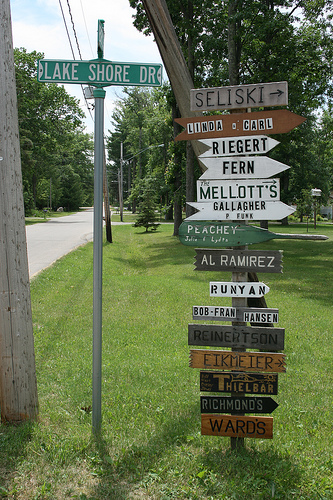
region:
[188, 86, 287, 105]
Sign for the Seliski family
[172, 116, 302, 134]
Sign for Linda and Carl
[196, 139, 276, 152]
Sign for the Riegert Family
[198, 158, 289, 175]
Sign for the Fern family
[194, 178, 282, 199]
Sign for the Mellott famliy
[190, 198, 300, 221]
Sign for the Gallagher family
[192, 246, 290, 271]
Sign for Al Ramirez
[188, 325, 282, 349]
Sign for the Reinertson family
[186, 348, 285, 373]
Sign for the Eikmeier family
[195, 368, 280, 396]
Sign for the Thielbar family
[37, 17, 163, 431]
Green street sign with white lettering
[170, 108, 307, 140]
Brown arrow sign with white and black name letters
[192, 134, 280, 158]
White arrow sign with black letters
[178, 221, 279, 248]
Green arrow sign with white letters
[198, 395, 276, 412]
Black arrow sign with white letters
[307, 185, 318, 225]
White bird house on a pole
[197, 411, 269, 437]
Wood sign with black letters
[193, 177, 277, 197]
White rectangle sign with black letters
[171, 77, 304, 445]
Fifteen signs on a pole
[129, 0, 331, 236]
Several tall green trees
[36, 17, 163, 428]
street signs on a pole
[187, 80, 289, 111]
rectangular wooden sign at the top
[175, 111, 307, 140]
brown arrow-shaped sign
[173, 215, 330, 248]
green wooden paddle sign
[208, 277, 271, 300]
small white arrow-shaped sign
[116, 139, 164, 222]
streetlight beside the road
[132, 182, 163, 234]
small pine tree near the road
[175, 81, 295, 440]
stack of signs with the residents' names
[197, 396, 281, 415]
black arrow-shaped sign towards the bottom of the stack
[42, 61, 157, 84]
white letters on the green sign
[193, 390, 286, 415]
Brown arrow sign with white letters.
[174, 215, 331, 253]
Green wooden sign shaped like a boat oar.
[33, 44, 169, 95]
Green street sign on post.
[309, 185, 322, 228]
White bird house on post.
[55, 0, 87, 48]
Electrical wires in the sky.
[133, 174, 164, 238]
Green pine tree in grass.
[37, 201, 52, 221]
Mailbox beside paved road.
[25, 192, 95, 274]
Paved street road in neighborhood.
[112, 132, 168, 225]
Metal street light beside road.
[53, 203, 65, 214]
Landscape rock on the ground.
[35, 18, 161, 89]
green street signs on pole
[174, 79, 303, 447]
several signs with last names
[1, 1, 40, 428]
wooden telephone pole in ground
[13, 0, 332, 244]
several large trees with green leaves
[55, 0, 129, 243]
power lines and telephone poles in a row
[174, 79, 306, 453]
last name signs are painted and wooden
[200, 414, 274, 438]
sign says WARD'S in black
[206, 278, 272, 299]
white sign says RUNYAN in black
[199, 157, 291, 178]
white arrow sign says FERN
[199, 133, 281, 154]
White arrow sign says REIGERT